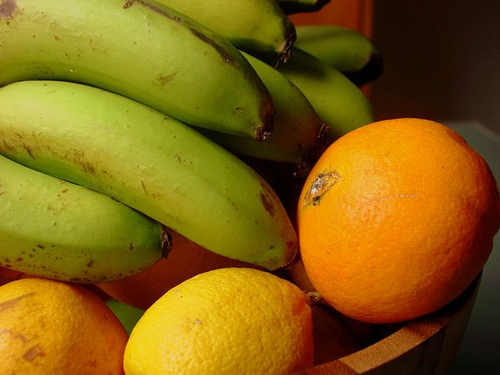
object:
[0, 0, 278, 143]
banana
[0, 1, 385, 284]
bunch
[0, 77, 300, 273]
banana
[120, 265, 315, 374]
lemon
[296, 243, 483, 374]
bowl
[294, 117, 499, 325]
orange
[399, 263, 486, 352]
edge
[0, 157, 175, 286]
banana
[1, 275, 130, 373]
orange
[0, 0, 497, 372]
fruit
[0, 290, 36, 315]
mark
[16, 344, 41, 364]
mark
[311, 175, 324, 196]
spot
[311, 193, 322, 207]
spot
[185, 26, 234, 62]
discoloration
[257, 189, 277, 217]
discoloration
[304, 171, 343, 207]
bruise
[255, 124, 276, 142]
stem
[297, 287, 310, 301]
stem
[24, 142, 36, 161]
spot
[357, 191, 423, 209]
scratches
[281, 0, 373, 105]
something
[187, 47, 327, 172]
banana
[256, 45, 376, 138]
banana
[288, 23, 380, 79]
banana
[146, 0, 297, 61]
banana